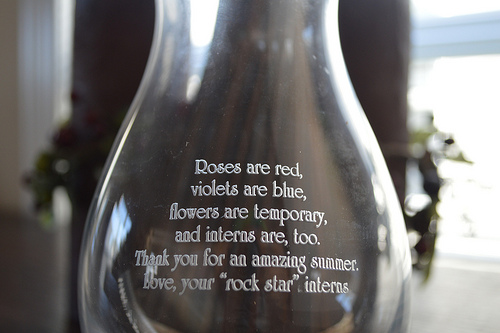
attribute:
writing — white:
[123, 132, 373, 314]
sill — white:
[388, 196, 488, 237]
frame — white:
[403, 9, 498, 292]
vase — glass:
[177, 55, 332, 225]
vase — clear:
[72, 3, 416, 328]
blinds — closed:
[2, 3, 73, 231]